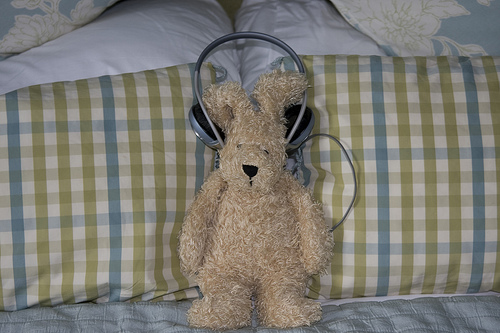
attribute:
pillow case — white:
[48, 51, 82, 60]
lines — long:
[281, 60, 497, 305]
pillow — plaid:
[268, 49, 491, 296]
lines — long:
[288, 51, 493, 289]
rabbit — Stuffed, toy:
[179, 69, 331, 329]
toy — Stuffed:
[179, 74, 331, 324]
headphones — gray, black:
[188, 27, 318, 147]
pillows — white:
[1, 5, 386, 95]